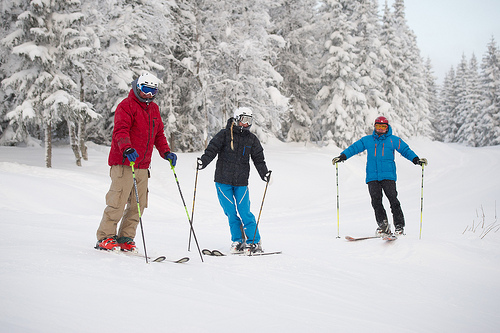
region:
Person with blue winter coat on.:
[332, 113, 428, 244]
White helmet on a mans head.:
[135, 72, 160, 99]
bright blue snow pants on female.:
[212, 180, 263, 252]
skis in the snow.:
[50, 222, 192, 268]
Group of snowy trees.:
[427, 55, 484, 145]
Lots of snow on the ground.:
[298, 251, 365, 307]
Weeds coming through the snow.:
[467, 205, 498, 240]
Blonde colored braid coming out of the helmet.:
[229, 117, 236, 149]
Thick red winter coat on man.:
[107, 88, 169, 169]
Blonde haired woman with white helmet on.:
[195, 102, 272, 254]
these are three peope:
[78, 70, 419, 268]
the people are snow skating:
[91, 65, 449, 265]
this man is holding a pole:
[331, 159, 343, 235]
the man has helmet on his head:
[140, 75, 154, 83]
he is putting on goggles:
[141, 89, 154, 93]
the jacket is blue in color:
[368, 135, 395, 183]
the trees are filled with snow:
[4, 0, 394, 72]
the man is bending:
[206, 105, 271, 250]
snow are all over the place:
[0, 267, 491, 330]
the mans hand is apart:
[398, 148, 422, 164]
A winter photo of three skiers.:
[1, 0, 498, 330]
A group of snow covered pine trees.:
[1, 0, 495, 76]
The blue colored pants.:
[210, 177, 262, 242]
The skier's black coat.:
[195, 121, 270, 181]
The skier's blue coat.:
[340, 131, 420, 177]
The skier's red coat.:
[108, 88, 170, 167]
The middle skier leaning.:
[196, 100, 273, 260]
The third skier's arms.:
[333, 136, 425, 168]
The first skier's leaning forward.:
[93, 73, 186, 269]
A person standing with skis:
[332, 103, 447, 253]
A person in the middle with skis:
[192, 91, 303, 265]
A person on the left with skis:
[58, 65, 206, 266]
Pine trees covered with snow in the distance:
[423, 34, 499, 151]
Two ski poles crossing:
[176, 156, 208, 269]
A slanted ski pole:
[243, 172, 279, 260]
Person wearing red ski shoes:
[93, 222, 140, 255]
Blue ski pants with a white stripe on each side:
[213, 182, 265, 247]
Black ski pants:
[360, 180, 412, 240]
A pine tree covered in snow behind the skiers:
[1, 1, 102, 173]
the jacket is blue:
[334, 124, 414, 194]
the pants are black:
[352, 173, 417, 239]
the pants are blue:
[212, 172, 268, 278]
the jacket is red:
[101, 97, 167, 173]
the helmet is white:
[129, 70, 170, 106]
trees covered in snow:
[159, 20, 366, 92]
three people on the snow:
[82, 51, 479, 298]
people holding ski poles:
[97, 140, 449, 265]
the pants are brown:
[100, 155, 162, 251]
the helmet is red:
[364, 114, 398, 135]